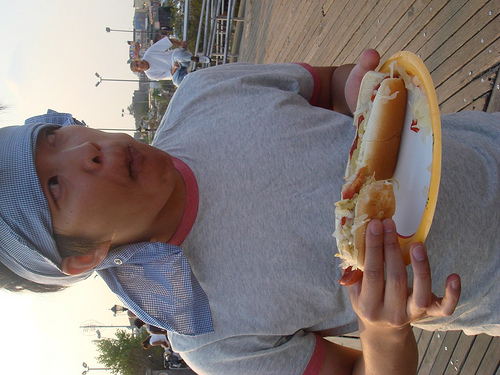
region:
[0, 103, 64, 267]
boy has blue bandanna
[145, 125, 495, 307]
boy has grey shirt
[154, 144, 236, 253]
shirt has pink collar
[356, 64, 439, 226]
white and yellow plate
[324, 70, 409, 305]
two hot dogs on plate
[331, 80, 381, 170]
ketchup on hot dog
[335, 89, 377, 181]
mustard on hot dog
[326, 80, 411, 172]
onions on hot dog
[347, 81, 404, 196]
light brown buns for hot dog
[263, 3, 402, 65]
light brown deck behind boy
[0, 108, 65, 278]
boy has grey headband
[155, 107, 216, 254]
red collar on shirt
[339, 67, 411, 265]
hot dogs on plate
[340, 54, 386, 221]
hot dog in light brown bun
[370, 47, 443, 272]
plate is round and yellow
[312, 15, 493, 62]
light brown deck behind boy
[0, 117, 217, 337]
Blue shirt on a man's head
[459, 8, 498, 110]
Nails in wooden planks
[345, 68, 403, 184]
Hot dog on a paper plate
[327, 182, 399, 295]
Man holding a hot dog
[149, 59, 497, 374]
Man wearing a gray shirt with red stripes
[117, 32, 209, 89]
Man sitting on a metal railing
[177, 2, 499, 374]
Wooden floor beneath a man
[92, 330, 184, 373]
Tree behind a woman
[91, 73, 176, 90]
Lights on a pole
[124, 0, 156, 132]
Buildings behind a man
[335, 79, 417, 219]
this is a hot dog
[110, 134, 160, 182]
the mouth of a person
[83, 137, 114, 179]
the nose of a person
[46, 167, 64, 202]
this is an eye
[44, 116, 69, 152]
this is an eye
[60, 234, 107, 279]
this is an ear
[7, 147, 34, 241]
a piece of clothe on the head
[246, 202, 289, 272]
this is a grey t shirt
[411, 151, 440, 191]
this is a flat plate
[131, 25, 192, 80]
this is a person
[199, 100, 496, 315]
the shirt is grey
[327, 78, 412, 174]
hot dog is on the plate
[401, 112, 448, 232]
the plate is yellow and white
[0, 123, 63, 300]
head scarf is on the head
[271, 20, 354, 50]
the fllor is wooden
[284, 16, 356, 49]
the floor is brown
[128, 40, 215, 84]
the man is sitted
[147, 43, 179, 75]
the tshirt is white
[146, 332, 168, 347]
the tshirt is white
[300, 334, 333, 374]
the sleeve are red